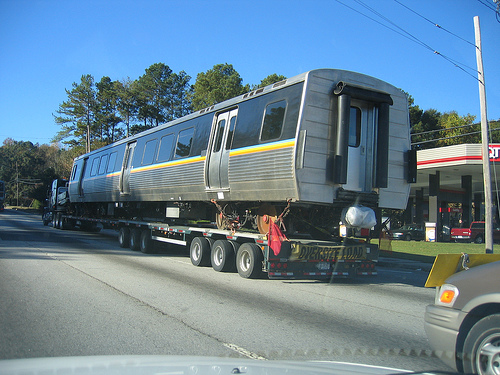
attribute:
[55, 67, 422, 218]
train car — loaded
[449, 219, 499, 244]
truck — red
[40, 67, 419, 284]
truck — grey, semi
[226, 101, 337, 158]
window — small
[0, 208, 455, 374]
road — paved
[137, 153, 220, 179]
stripe — yellow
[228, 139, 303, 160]
stripe — yellow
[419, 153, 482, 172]
stripe — yellow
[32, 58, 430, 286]
car — train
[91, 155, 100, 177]
window — small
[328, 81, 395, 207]
door — white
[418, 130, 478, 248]
station — gas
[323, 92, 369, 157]
window — small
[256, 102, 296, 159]
window — small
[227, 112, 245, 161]
window — small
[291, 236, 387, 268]
sign — black, yellow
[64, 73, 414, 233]
train — metal